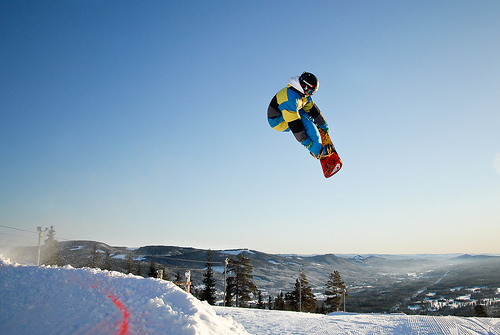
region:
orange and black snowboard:
[318, 150, 342, 177]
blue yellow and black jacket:
[263, 87, 343, 156]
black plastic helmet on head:
[301, 71, 318, 90]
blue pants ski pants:
[290, 112, 323, 159]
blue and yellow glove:
[311, 143, 328, 160]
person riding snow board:
[259, 73, 342, 180]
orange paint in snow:
[108, 285, 130, 333]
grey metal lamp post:
[223, 257, 228, 307]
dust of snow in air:
[7, 225, 62, 266]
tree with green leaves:
[231, 250, 258, 310]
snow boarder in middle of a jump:
[233, 58, 384, 186]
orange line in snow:
[76, 273, 141, 334]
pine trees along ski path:
[283, 260, 360, 310]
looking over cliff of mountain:
[6, 181, 494, 316]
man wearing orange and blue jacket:
[247, 54, 389, 179]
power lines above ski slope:
[1, 190, 62, 282]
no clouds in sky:
[0, 5, 497, 261]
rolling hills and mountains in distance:
[25, 216, 497, 312]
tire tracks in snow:
[421, 310, 492, 330]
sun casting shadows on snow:
[90, 268, 259, 334]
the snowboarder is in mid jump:
[256, 68, 351, 181]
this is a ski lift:
[2, 216, 352, 313]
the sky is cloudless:
[1, 0, 494, 240]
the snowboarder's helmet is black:
[296, 66, 321, 93]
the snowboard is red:
[316, 118, 343, 178]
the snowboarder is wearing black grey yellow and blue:
[262, 69, 336, 162]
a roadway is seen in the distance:
[386, 264, 455, 307]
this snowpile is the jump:
[2, 256, 260, 330]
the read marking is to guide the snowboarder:
[84, 278, 131, 334]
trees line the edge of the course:
[45, 225, 360, 315]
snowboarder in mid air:
[255, 59, 365, 177]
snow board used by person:
[318, 127, 344, 180]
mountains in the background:
[141, 242, 348, 276]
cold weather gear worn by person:
[265, 89, 334, 146]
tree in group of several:
[227, 247, 259, 304]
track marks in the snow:
[417, 314, 446, 334]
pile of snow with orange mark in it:
[0, 258, 245, 333]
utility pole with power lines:
[33, 221, 49, 271]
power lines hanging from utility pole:
[2, 219, 35, 250]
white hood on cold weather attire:
[288, 75, 303, 92]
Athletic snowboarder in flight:
[266, 67, 346, 179]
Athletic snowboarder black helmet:
[298, 67, 320, 95]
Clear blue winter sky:
[31, 57, 106, 107]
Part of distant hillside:
[264, 254, 297, 273]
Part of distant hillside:
[351, 260, 382, 278]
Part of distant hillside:
[417, 257, 437, 270]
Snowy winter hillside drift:
[137, 294, 175, 324]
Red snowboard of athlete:
[320, 141, 343, 176]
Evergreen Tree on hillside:
[320, 270, 345, 315]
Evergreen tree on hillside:
[293, 270, 316, 310]